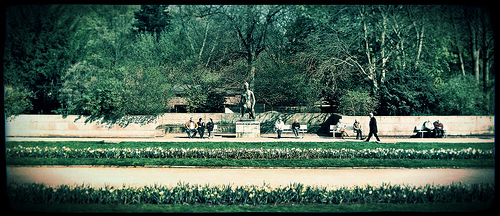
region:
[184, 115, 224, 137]
people sitting on park bench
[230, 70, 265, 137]
statue in center of park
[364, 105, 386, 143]
person walking in park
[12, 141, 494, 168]
row of flowers in park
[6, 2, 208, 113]
trees in back of people sitting on bench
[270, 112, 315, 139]
two people sitting on another bench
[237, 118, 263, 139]
base of statue in park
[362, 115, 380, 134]
jacket worn by man walking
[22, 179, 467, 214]
row of flowers furthest from park sitters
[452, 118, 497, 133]
wall behind park sitters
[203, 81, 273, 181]
statue on a stand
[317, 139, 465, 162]
group of white flowers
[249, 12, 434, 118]
green trees and brown branches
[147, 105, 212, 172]
three people sitting on bench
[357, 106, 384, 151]
person wearing all black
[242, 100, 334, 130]
shade on the concrete wall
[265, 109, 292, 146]
person wearing white shirt and blue jeans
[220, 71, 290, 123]
indian statue standing on square pillow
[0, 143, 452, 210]
pond of water with flowers around it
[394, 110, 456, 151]
two people sitting on bench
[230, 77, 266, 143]
A statue on a pedestal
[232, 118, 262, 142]
a pedestal holding a statue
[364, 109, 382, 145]
a man in a dark coat walking on a sidewalk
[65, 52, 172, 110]
a tree with green leaves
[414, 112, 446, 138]
two people sitting on a bench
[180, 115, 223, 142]
three people sitting on a bench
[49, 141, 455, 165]
a row of flowers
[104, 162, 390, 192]
some water in a park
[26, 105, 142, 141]
a cement wall in a park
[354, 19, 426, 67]
some trees in the background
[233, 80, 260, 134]
statue on pedestal in park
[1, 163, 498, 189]
body of water in park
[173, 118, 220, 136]
three people sitting on bench in park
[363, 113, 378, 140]
man walking in black suit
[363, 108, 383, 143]
man with gray hair in park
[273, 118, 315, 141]
man sitting alone in park on bench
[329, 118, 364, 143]
person in brown hoodie sitting alone on bench in park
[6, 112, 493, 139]
concrete wall surrounding park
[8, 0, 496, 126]
green trees lining park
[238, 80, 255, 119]
green statue of kneeling man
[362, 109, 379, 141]
Person wearing all black walking down the path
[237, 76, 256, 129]
Tall green colored statue of a figure on a marble pedestal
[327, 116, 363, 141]
A white painted bench near a wall with two people on it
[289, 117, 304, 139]
A person wearing a dark shirt and blue jeans sitting on a bench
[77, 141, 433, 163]
A row of white colored flowers on a green strip of grass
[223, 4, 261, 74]
Tall thick trunk of a tree with many thick branches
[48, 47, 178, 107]
Thick green clump of shrubbery and leaves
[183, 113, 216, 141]
Three people sharing the same white bench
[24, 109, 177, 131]
Tall white wall in front of trees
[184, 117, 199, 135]
Person wearing a brown jacket over a white shirt